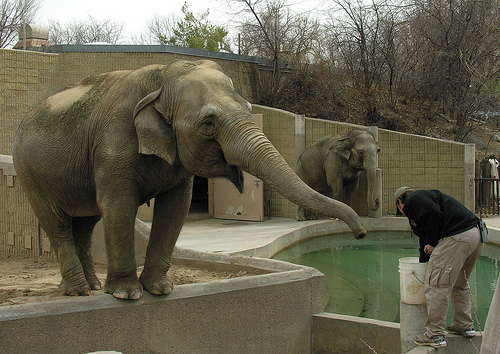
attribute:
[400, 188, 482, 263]
shirt — black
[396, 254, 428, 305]
bucket — white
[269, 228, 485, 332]
water — green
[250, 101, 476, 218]
wall — cement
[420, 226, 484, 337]
pants — khaki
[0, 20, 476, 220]
building — cement block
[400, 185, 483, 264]
sweatshirt — black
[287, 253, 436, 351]
pool — green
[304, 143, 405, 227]
elephant — grey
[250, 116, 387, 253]
trunk — grey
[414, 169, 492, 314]
man — bent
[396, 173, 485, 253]
coat — black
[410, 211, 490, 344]
pants — tan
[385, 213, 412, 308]
bucket — white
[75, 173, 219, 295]
elephant — grey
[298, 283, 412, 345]
cement — grey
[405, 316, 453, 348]
shoe — grey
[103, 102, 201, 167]
ear — grey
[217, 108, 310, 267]
door — tan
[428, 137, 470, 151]
brick — yellow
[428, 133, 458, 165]
brick — yellow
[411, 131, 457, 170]
brick — yellow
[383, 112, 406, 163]
brick — yellow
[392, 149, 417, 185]
brick — yellow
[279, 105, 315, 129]
brick — yellow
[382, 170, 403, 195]
brick — yellow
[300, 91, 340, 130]
brick — yellow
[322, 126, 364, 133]
brick — yellow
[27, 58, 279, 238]
elephant — grey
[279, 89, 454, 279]
elephant — grey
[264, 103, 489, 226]
wall — stone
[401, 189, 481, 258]
jacket — black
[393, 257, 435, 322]
bucket — large, white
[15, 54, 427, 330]
elephant — gray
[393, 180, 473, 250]
jacket — black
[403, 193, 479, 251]
jacket — black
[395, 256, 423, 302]
bucket — white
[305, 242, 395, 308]
water — pale green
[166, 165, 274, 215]
door — open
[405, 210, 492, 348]
pants — khaki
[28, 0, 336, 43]
sky — white